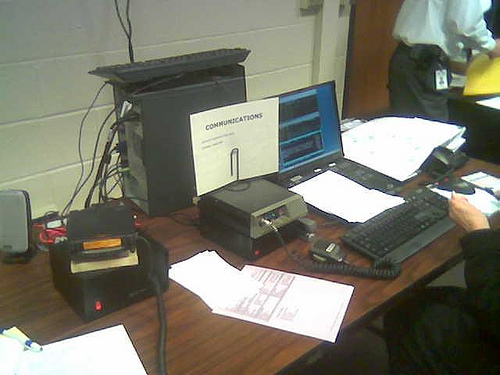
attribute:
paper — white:
[209, 262, 361, 352]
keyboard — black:
[342, 189, 473, 268]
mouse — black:
[437, 172, 477, 196]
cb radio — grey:
[197, 172, 312, 242]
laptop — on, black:
[252, 80, 411, 222]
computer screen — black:
[274, 83, 342, 166]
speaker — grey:
[0, 183, 34, 259]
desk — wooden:
[2, 110, 497, 372]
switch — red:
[88, 296, 104, 316]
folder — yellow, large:
[461, 44, 500, 102]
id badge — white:
[436, 66, 452, 95]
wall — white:
[1, 8, 364, 235]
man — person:
[376, 180, 500, 372]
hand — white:
[443, 197, 487, 232]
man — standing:
[390, 2, 500, 124]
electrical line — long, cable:
[94, 111, 140, 208]